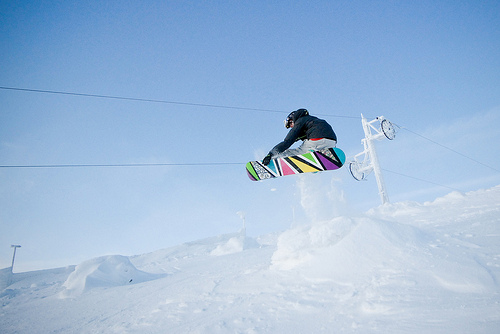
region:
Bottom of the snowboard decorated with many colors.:
[228, 147, 349, 184]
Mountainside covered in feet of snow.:
[2, 181, 497, 329]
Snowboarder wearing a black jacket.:
[253, 104, 347, 141]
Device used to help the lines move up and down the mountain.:
[347, 102, 412, 212]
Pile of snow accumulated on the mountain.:
[51, 250, 173, 297]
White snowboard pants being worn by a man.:
[270, 132, 339, 160]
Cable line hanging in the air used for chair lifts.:
[0, 145, 237, 193]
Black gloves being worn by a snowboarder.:
[255, 149, 279, 169]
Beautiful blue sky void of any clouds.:
[5, 5, 489, 75]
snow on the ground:
[247, 282, 336, 295]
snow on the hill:
[122, 280, 244, 325]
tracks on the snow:
[355, 245, 484, 318]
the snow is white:
[280, 243, 389, 300]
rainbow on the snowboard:
[242, 163, 344, 168]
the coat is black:
[297, 118, 327, 135]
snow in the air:
[287, 191, 347, 241]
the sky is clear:
[84, 173, 184, 225]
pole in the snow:
[5, 228, 31, 274]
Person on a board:
[246, 145, 351, 187]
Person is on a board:
[243, 145, 350, 184]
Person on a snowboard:
[243, 145, 349, 182]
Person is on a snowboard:
[241, 144, 353, 184]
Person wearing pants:
[270, 134, 340, 160]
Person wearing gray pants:
[265, 134, 337, 154]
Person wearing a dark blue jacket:
[263, 107, 338, 156]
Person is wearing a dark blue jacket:
[266, 110, 341, 157]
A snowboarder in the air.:
[233, 105, 357, 190]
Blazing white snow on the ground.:
[98, 263, 421, 306]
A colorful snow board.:
[240, 144, 346, 180]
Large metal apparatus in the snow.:
[338, 105, 408, 210]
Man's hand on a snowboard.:
[251, 150, 281, 168]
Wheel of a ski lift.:
[380, 118, 395, 144]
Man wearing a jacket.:
[252, 102, 342, 163]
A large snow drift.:
[56, 248, 178, 305]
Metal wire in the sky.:
[21, 154, 231, 178]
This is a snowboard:
[219, 148, 371, 200]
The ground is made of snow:
[49, 239, 412, 319]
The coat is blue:
[256, 101, 355, 161]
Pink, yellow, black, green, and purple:
[231, 143, 375, 193]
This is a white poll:
[334, 106, 426, 221]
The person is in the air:
[234, 90, 366, 202]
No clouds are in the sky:
[64, 6, 303, 100]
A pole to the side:
[3, 230, 33, 283]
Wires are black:
[15, 64, 479, 224]